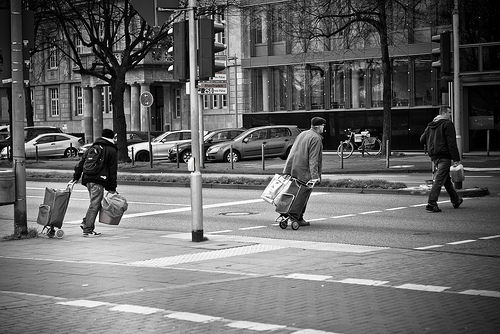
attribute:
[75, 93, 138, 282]
man — crossing the stret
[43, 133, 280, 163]
cars — parked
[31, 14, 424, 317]
shade — black, white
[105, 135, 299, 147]
cars — parked